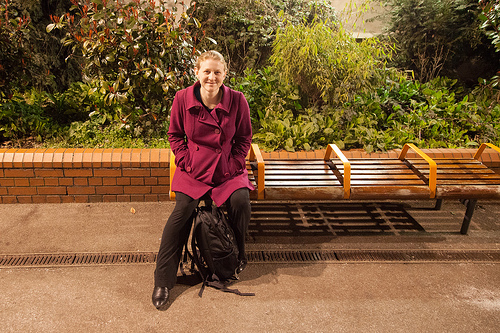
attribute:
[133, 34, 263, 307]
woman — sitting, smiling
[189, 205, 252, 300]
backpack — black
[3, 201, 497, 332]
ground — brown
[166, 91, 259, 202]
jacket — red, maroon, pink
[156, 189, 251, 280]
pants — black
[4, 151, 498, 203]
wall — brick, small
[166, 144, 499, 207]
bench — wooden, spacious, long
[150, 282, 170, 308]
shoe — black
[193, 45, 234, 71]
hair — blonde